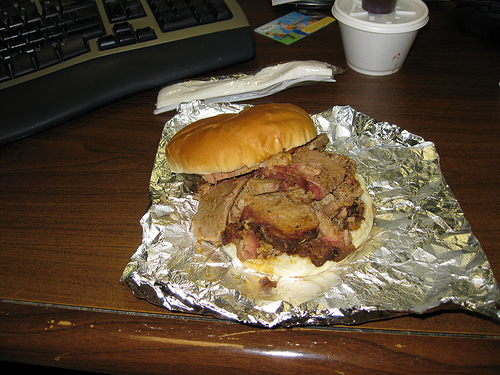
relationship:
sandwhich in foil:
[173, 105, 375, 274] [122, 96, 498, 324]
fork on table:
[154, 67, 343, 105] [1, 40, 499, 370]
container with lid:
[336, 25, 416, 76] [337, 0, 432, 28]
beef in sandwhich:
[202, 165, 359, 264] [173, 105, 375, 274]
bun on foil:
[161, 105, 336, 164] [122, 96, 498, 324]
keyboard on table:
[0, 0, 243, 142] [1, 40, 499, 370]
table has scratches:
[1, 40, 499, 370] [12, 303, 298, 351]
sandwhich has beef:
[173, 105, 375, 274] [202, 165, 359, 264]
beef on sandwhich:
[202, 165, 359, 264] [173, 105, 375, 274]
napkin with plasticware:
[151, 72, 341, 97] [140, 51, 348, 102]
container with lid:
[329, 0, 433, 77] [337, 0, 432, 28]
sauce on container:
[366, 0, 398, 14] [329, 0, 433, 77]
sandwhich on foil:
[173, 105, 375, 274] [122, 96, 498, 324]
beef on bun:
[188, 147, 366, 268] [161, 105, 336, 164]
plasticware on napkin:
[140, 51, 348, 102] [151, 72, 341, 97]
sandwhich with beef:
[173, 105, 375, 274] [188, 147, 366, 268]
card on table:
[259, 6, 337, 48] [1, 40, 499, 370]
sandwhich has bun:
[173, 105, 375, 274] [161, 105, 336, 164]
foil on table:
[122, 96, 498, 324] [1, 40, 499, 370]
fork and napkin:
[154, 67, 343, 105] [151, 72, 341, 97]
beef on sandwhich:
[188, 147, 366, 268] [173, 105, 375, 274]